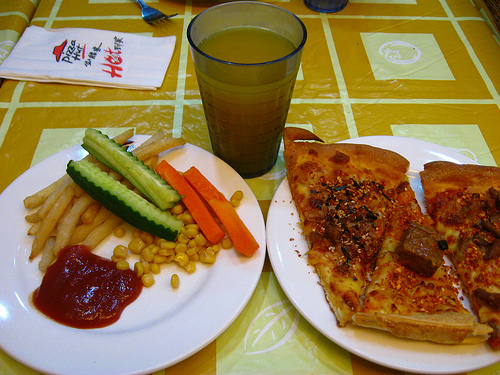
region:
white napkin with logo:
[0, 10, 182, 89]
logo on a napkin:
[45, 33, 92, 65]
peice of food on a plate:
[63, 153, 190, 239]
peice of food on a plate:
[75, 125, 184, 210]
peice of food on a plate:
[154, 153, 230, 245]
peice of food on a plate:
[182, 160, 263, 265]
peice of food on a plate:
[280, 126, 406, 333]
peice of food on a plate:
[348, 166, 480, 358]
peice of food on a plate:
[418, 153, 498, 360]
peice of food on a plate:
[166, 270, 186, 292]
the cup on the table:
[186, 1, 308, 178]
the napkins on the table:
[0, 24, 176, 89]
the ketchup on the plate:
[30, 244, 142, 329]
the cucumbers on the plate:
[66, 127, 183, 241]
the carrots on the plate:
[155, 160, 260, 257]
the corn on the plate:
[110, 190, 243, 288]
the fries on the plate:
[24, 127, 185, 272]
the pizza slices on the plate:
[284, 125, 499, 350]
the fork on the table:
[135, 0, 179, 25]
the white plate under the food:
[1, 133, 266, 372]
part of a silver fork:
[133, 0, 178, 30]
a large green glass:
[180, 0, 304, 175]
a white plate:
[260, 133, 487, 374]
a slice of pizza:
[285, 134, 409, 332]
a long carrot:
[184, 165, 260, 260]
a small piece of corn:
[167, 272, 180, 289]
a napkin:
[0, 15, 177, 97]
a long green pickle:
[60, 156, 187, 241]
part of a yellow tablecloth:
[162, 290, 356, 374]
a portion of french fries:
[24, 175, 118, 265]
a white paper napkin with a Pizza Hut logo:
[4, 29, 176, 94]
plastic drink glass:
[186, 5, 306, 179]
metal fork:
[138, 3, 171, 25]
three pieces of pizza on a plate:
[290, 133, 497, 344]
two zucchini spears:
[65, 126, 182, 238]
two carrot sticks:
[157, 160, 256, 255]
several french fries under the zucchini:
[25, 128, 183, 258]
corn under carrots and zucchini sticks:
[115, 193, 242, 296]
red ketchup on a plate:
[32, 245, 139, 327]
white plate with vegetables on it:
[0, 133, 263, 373]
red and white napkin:
[51, 42, 137, 90]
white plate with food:
[23, 196, 174, 312]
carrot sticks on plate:
[176, 170, 220, 248]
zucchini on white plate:
[90, 131, 172, 238]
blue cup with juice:
[221, 89, 253, 157]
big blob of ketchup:
[35, 269, 138, 321]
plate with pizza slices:
[288, 161, 497, 351]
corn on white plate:
[131, 238, 162, 260]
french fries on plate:
[48, 205, 95, 239]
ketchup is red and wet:
[51, 275, 113, 312]